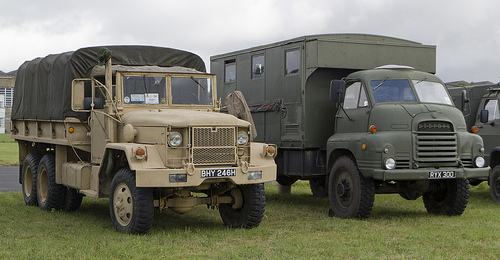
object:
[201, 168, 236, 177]
license plate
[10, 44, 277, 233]
truck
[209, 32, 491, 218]
truck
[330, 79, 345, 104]
mirror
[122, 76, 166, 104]
windshield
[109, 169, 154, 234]
tire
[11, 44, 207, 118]
tarp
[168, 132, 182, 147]
headlight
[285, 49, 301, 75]
window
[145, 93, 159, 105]
paper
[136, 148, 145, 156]
light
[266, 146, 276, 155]
light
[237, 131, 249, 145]
headlight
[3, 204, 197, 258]
grass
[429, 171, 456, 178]
license plate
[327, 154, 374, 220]
tire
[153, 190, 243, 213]
axle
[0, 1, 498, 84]
sky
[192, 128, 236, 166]
grill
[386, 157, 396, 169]
headlight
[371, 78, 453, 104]
windshield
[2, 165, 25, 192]
road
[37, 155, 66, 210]
tire